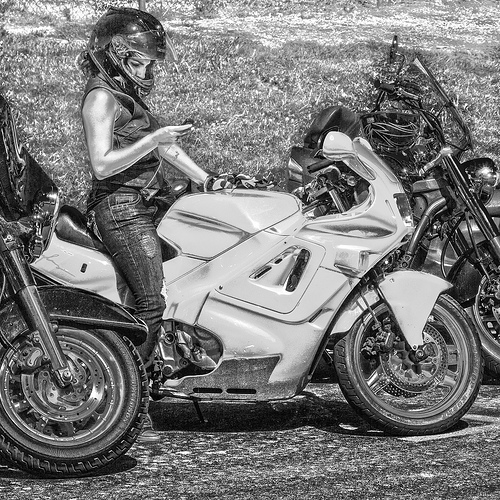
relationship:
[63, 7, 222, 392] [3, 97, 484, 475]
woman sitting motorcycle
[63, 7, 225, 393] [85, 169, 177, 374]
woman wearing jeans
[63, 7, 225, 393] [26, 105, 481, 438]
woman sitting bike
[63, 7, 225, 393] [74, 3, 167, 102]
woman wearing head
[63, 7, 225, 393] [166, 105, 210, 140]
woman holding cellphone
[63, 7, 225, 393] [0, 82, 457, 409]
woman on bike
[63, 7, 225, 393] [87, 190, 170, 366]
woman wearing jeans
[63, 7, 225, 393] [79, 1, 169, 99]
woman wearing helmet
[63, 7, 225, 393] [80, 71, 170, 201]
woman wearing jacket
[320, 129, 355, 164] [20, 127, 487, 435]
mirror on motorcycle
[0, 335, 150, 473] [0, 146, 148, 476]
front tire of motorcycle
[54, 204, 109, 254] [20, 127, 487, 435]
seat on motorcycle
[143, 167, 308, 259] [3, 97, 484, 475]
tank of motorcycle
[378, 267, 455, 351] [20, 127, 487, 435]
fender of motorcycle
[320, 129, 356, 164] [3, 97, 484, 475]
mirror of motorcycle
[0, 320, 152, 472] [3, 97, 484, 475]
front tire of motorcycle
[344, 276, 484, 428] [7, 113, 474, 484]
tire of motorbike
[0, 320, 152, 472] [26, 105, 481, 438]
front tire of bike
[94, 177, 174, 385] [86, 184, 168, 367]
leg in jeans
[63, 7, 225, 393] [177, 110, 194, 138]
woman holding object